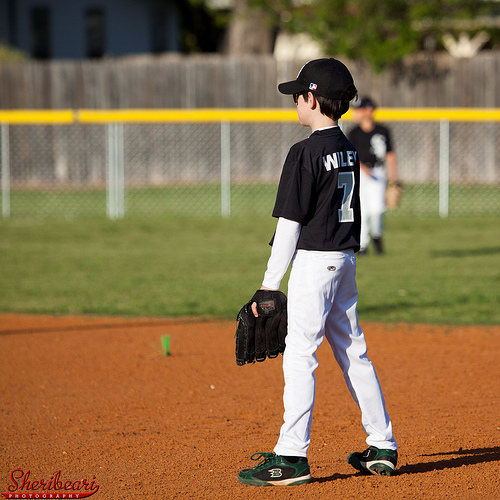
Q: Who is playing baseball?
A: A boy.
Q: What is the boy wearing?
A: A uniform.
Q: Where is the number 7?
A: On the boy's back.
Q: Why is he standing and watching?
A: He is waiting for a play.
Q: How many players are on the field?
A: Two.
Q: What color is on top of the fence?
A: Yellow.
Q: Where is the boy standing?
A: In the infield.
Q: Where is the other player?
A: Standing in the grass.